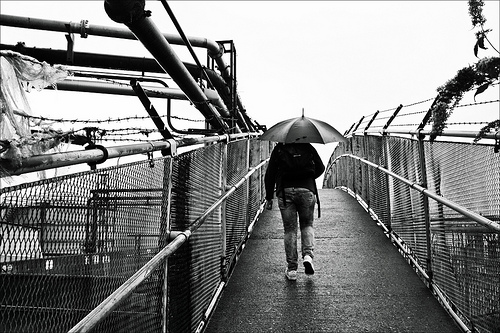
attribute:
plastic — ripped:
[3, 59, 31, 111]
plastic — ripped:
[3, 67, 61, 84]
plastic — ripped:
[0, 115, 33, 135]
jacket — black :
[277, 152, 314, 194]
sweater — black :
[264, 140, 327, 201]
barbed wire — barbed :
[337, 89, 494, 132]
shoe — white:
[302, 253, 317, 277]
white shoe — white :
[280, 266, 304, 292]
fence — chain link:
[2, 131, 270, 331]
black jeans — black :
[266, 181, 321, 281]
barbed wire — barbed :
[1, 50, 263, 150]